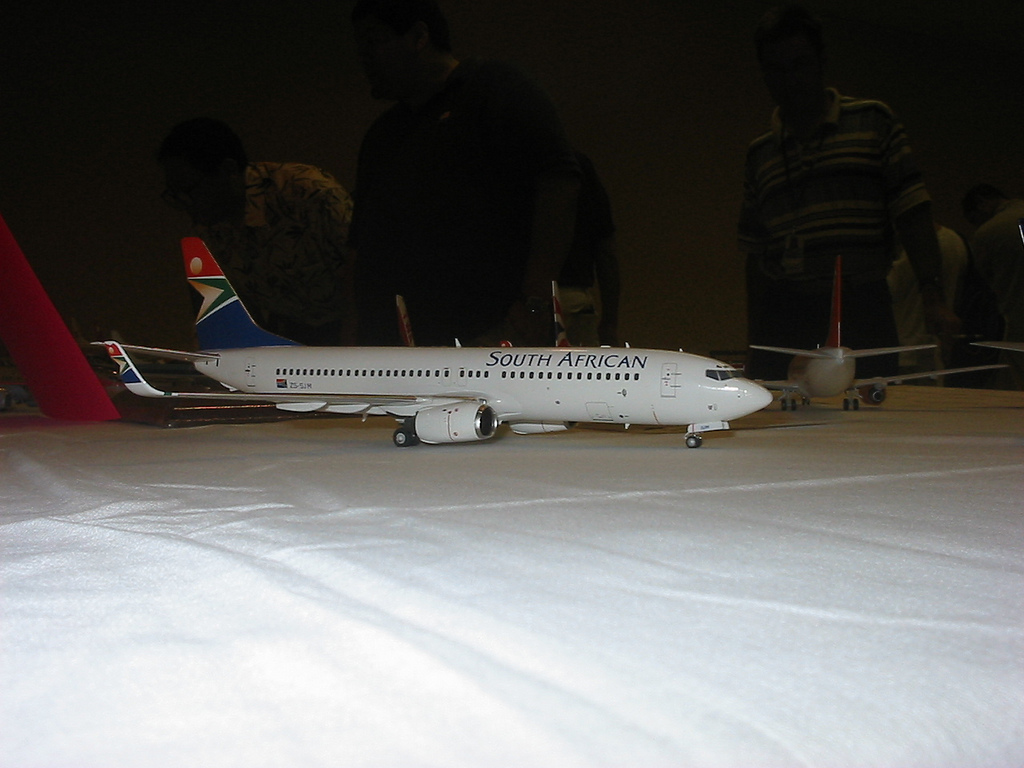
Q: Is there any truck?
A: No, there are no trucks.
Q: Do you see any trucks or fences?
A: No, there are no trucks or fences.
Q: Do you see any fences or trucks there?
A: No, there are no trucks or fences.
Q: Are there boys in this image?
A: No, there are no boys.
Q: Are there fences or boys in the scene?
A: No, there are no boys or fences.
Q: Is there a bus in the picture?
A: No, there are no buses.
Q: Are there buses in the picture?
A: No, there are no buses.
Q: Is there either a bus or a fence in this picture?
A: No, there are no buses or fences.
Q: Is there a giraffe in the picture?
A: No, there are no giraffes.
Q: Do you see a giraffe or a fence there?
A: No, there are no giraffes or fences.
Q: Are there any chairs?
A: No, there are no chairs.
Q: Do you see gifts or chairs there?
A: No, there are no chairs or gifts.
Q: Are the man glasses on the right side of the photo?
A: Yes, the glasses are on the right of the image.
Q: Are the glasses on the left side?
A: No, the glasses are on the right of the image.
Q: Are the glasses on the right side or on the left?
A: The glasses are on the right of the image.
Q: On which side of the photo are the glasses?
A: The glasses are on the right of the image.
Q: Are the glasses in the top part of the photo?
A: Yes, the glasses are in the top of the image.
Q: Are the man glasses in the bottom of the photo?
A: No, the glasses are in the top of the image.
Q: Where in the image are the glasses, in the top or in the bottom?
A: The glasses are in the top of the image.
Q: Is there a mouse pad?
A: No, there are no mouse pads.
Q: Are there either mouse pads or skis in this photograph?
A: No, there are no mouse pads or skis.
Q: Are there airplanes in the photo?
A: Yes, there is an airplane.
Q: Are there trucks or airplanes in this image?
A: Yes, there is an airplane.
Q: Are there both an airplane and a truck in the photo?
A: No, there is an airplane but no trucks.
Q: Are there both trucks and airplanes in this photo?
A: No, there is an airplane but no trucks.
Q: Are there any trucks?
A: No, there are no trucks.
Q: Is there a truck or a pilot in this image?
A: No, there are no trucks or pilots.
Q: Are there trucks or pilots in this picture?
A: No, there are no trucks or pilots.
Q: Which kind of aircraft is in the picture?
A: The aircraft is an airplane.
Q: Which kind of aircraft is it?
A: The aircraft is an airplane.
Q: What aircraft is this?
A: This is an airplane.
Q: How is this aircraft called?
A: This is an airplane.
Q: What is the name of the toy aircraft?
A: The aircraft is an airplane.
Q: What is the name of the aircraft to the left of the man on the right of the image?
A: The aircraft is an airplane.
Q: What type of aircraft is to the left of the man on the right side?
A: The aircraft is an airplane.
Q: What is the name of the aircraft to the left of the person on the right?
A: The aircraft is an airplane.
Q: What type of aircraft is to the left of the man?
A: The aircraft is an airplane.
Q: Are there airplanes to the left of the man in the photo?
A: Yes, there is an airplane to the left of the man.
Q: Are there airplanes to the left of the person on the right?
A: Yes, there is an airplane to the left of the man.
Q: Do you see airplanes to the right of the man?
A: No, the airplane is to the left of the man.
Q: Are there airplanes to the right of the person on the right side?
A: No, the airplane is to the left of the man.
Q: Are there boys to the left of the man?
A: No, there is an airplane to the left of the man.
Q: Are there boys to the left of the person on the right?
A: No, there is an airplane to the left of the man.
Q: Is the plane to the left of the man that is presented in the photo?
A: Yes, the plane is to the left of the man.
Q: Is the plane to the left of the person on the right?
A: Yes, the plane is to the left of the man.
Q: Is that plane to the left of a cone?
A: No, the plane is to the left of the man.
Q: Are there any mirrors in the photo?
A: No, there are no mirrors.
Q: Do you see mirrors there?
A: No, there are no mirrors.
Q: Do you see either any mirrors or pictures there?
A: No, there are no mirrors or pictures.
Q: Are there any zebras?
A: No, there are no zebras.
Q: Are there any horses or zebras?
A: No, there are no zebras or horses.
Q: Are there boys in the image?
A: No, there are no boys.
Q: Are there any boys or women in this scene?
A: No, there are no boys or women.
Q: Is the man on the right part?
A: Yes, the man is on the right of the image.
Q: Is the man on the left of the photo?
A: No, the man is on the right of the image.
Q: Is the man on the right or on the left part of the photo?
A: The man is on the right of the image.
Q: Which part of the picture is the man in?
A: The man is on the right of the image.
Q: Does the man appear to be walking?
A: Yes, the man is walking.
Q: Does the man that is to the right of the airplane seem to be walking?
A: Yes, the man is walking.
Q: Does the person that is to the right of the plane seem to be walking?
A: Yes, the man is walking.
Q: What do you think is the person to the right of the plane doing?
A: The man is walking.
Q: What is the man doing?
A: The man is walking.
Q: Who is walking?
A: The man is walking.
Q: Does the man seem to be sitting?
A: No, the man is walking.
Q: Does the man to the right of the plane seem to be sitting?
A: No, the man is walking.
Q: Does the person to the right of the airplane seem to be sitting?
A: No, the man is walking.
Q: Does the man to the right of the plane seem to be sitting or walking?
A: The man is walking.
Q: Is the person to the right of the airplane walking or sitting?
A: The man is walking.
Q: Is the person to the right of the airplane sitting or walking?
A: The man is walking.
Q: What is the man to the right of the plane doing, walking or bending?
A: The man is walking.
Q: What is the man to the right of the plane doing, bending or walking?
A: The man is walking.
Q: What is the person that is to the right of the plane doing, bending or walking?
A: The man is walking.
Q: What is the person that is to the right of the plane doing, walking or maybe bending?
A: The man is walking.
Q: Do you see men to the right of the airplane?
A: Yes, there is a man to the right of the airplane.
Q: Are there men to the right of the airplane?
A: Yes, there is a man to the right of the airplane.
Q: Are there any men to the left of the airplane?
A: No, the man is to the right of the airplane.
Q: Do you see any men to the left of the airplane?
A: No, the man is to the right of the airplane.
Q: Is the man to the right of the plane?
A: Yes, the man is to the right of the plane.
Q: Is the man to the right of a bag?
A: No, the man is to the right of the plane.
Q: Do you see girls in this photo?
A: No, there are no girls.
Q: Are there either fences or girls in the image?
A: No, there are no girls or fences.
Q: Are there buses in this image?
A: No, there are no buses.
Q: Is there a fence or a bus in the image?
A: No, there are no buses or fences.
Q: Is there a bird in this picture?
A: No, there are no birds.